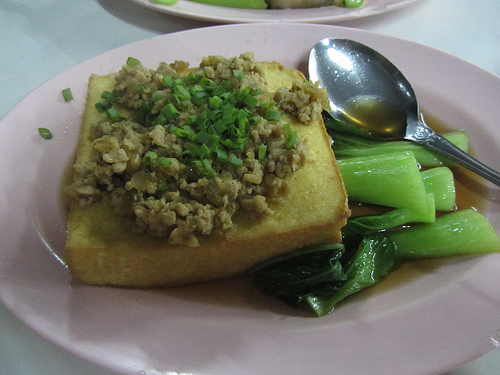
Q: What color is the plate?
A: White.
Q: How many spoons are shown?
A: One.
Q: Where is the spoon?
A: On the plate.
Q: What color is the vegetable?
A: Green.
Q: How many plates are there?
A: Two.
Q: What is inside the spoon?
A: Sauce.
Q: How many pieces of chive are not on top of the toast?
A: Two.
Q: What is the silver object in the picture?
A: Spoon.